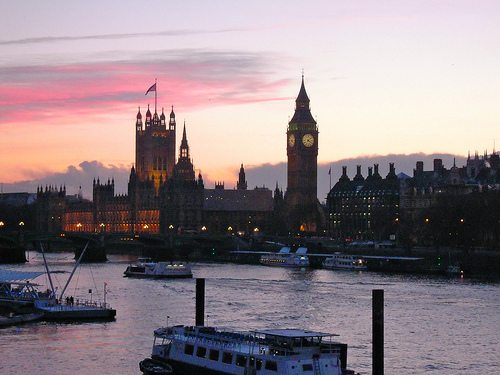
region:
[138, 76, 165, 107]
flag on top of building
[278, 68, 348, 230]
clock tower across river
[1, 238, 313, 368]
boats on river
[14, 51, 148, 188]
sky is red and orange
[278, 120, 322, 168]
clock is large and round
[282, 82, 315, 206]
clock is city landmark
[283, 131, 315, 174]
clock is lit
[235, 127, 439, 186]
clouds behind clock tower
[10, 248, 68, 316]
people standing on leftmost boat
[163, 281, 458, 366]
water has few ripples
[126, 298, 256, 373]
the boat is white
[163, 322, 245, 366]
the boat is white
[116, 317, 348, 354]
the boat is white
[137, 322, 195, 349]
the boat is white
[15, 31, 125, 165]
Pink clouds in sunset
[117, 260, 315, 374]
white boat at pier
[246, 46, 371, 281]
large clock tower on waterfront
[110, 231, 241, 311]
white boat on water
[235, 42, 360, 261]
lit large clock tower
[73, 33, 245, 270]
Flag blowing in wind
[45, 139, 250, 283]
Lit up large building on waterfront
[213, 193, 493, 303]
water front town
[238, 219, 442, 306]
white boats docked at pier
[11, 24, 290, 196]
Pink and blue clouds at sunset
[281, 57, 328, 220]
the clock tower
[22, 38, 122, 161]
the sun is setting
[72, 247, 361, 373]
the boats on the water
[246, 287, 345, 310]
the water is calm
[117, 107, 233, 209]
the castle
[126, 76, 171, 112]
the flag on top of the castle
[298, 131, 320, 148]
the clock on the tower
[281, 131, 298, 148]
the clock on the tower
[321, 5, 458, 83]
the sky is clear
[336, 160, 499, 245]
the building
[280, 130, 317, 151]
large clocks on tower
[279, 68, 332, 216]
large stone clock tower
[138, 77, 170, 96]
flag flying on roof of building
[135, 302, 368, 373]
large white boat on water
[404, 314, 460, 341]
small ripples on water surface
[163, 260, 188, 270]
lights on back of boat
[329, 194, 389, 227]
windows on side of building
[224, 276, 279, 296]
boat ripples on water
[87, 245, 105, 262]
black stone bridge support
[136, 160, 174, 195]
lights shining on side of building